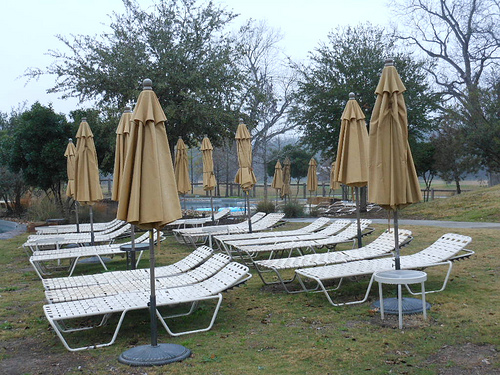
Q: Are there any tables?
A: Yes, there is a table.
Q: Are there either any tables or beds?
A: Yes, there is a table.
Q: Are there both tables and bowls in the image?
A: No, there is a table but no bowls.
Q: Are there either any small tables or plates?
A: Yes, there is a small table.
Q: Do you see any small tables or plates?
A: Yes, there is a small table.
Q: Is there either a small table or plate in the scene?
A: Yes, there is a small table.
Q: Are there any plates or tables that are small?
A: Yes, the table is small.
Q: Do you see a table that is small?
A: Yes, there is a small table.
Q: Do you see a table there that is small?
A: Yes, there is a table that is small.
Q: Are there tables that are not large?
A: Yes, there is a small table.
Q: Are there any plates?
A: No, there are no plates.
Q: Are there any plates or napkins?
A: No, there are no plates or napkins.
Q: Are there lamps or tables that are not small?
A: No, there is a table but it is small.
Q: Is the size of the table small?
A: Yes, the table is small.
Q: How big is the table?
A: The table is small.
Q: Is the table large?
A: No, the table is small.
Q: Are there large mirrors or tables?
A: No, there is a table but it is small.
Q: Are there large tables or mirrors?
A: No, there is a table but it is small.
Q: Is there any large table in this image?
A: No, there is a table but it is small.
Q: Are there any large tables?
A: No, there is a table but it is small.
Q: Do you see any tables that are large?
A: No, there is a table but it is small.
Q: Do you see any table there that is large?
A: No, there is a table but it is small.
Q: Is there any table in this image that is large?
A: No, there is a table but it is small.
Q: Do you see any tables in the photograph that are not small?
A: No, there is a table but it is small.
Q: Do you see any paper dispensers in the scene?
A: No, there are no paper dispensers.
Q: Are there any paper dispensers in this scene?
A: No, there are no paper dispensers.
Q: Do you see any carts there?
A: No, there are no carts.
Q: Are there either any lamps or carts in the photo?
A: No, there are no carts or lamps.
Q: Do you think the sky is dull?
A: Yes, the sky is dull.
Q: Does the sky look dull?
A: Yes, the sky is dull.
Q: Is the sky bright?
A: No, the sky is dull.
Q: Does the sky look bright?
A: No, the sky is dull.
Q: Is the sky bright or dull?
A: The sky is dull.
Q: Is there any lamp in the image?
A: No, there are no lamps.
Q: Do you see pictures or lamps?
A: No, there are no lamps or pictures.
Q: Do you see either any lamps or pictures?
A: No, there are no lamps or pictures.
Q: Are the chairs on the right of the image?
A: Yes, the chairs are on the right of the image.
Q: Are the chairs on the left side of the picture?
A: No, the chairs are on the right of the image.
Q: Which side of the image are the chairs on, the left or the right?
A: The chairs are on the right of the image.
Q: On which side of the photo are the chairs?
A: The chairs are on the right of the image.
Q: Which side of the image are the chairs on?
A: The chairs are on the right of the image.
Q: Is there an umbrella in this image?
A: Yes, there are umbrellas.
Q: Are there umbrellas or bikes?
A: Yes, there are umbrellas.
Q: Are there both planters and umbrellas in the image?
A: No, there are umbrellas but no planters.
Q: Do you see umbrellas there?
A: Yes, there is an umbrella.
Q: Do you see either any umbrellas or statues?
A: Yes, there is an umbrella.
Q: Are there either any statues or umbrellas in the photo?
A: Yes, there is an umbrella.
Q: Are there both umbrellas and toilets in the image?
A: No, there is an umbrella but no toilets.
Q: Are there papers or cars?
A: No, there are no cars or papers.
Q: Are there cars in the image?
A: No, there are no cars.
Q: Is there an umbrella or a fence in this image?
A: Yes, there is an umbrella.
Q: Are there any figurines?
A: No, there are no figurines.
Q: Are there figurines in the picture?
A: No, there are no figurines.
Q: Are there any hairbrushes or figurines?
A: No, there are no figurines or hairbrushes.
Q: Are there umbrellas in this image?
A: Yes, there is an umbrella.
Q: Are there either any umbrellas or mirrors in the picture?
A: Yes, there is an umbrella.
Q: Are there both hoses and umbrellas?
A: No, there is an umbrella but no hoses.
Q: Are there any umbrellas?
A: Yes, there is an umbrella.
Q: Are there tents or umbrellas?
A: Yes, there is an umbrella.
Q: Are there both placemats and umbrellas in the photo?
A: No, there is an umbrella but no placemats.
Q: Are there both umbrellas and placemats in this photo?
A: No, there is an umbrella but no placemats.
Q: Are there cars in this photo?
A: No, there are no cars.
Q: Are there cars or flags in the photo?
A: No, there are no cars or flags.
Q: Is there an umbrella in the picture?
A: Yes, there is an umbrella.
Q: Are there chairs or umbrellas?
A: Yes, there is an umbrella.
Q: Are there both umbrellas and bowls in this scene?
A: No, there is an umbrella but no bowls.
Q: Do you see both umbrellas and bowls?
A: No, there is an umbrella but no bowls.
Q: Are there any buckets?
A: No, there are no buckets.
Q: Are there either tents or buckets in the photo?
A: No, there are no buckets or tents.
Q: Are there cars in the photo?
A: No, there are no cars.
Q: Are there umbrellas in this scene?
A: Yes, there is an umbrella.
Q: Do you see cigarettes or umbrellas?
A: Yes, there is an umbrella.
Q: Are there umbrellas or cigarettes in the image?
A: Yes, there is an umbrella.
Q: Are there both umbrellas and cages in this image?
A: No, there is an umbrella but no cages.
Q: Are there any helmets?
A: No, there are no helmets.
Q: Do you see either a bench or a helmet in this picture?
A: No, there are no helmets or benches.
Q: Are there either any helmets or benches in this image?
A: No, there are no helmets or benches.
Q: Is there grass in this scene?
A: Yes, there is grass.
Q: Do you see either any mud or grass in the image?
A: Yes, there is grass.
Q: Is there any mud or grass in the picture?
A: Yes, there is grass.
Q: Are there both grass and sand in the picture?
A: No, there is grass but no sand.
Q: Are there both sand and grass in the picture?
A: No, there is grass but no sand.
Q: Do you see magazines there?
A: No, there are no magazines.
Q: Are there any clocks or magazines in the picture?
A: No, there are no magazines or clocks.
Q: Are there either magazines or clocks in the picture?
A: No, there are no magazines or clocks.